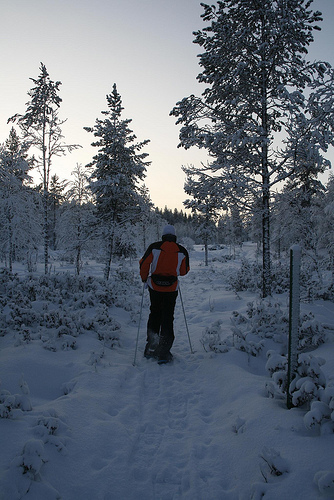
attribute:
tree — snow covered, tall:
[189, 4, 313, 243]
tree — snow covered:
[85, 71, 144, 253]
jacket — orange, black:
[145, 242, 190, 288]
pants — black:
[146, 294, 175, 350]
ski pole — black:
[180, 291, 199, 354]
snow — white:
[204, 278, 229, 307]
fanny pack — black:
[152, 273, 174, 287]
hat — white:
[159, 223, 180, 233]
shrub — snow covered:
[250, 315, 276, 349]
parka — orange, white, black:
[152, 247, 164, 272]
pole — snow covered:
[282, 290, 302, 378]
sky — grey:
[79, 23, 147, 64]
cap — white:
[162, 226, 174, 234]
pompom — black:
[165, 236, 170, 241]